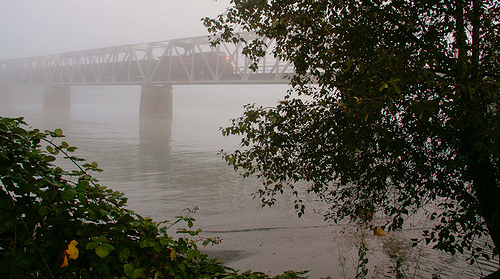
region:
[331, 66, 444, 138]
the tree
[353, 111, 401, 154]
the tree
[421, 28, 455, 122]
the tree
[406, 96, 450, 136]
the tree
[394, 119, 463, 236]
the tree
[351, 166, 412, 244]
the tree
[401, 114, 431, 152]
the tree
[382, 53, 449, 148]
the tree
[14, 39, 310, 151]
train bridge on the fog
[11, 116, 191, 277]
wet and green leaved bush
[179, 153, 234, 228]
ripples ans waves in the water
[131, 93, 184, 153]
pylon holding up the bridge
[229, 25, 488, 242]
tree near the river bank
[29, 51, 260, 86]
train driving over the bridge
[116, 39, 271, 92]
triangular design on the train bridge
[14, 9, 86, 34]
gray and foggy sky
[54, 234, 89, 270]
yellow leaf among the green ones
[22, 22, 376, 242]
foggy day by the river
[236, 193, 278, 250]
The water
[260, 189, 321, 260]
The water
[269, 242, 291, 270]
The water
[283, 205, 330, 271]
The water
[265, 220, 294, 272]
The water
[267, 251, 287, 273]
The water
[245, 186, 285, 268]
The water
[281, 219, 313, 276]
The water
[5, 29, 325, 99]
long covered bridge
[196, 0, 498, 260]
lush dense green trees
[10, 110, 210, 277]
dense green leafy bushes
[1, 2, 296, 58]
foggy gray misty sky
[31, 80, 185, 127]
grey concrete misty bridge supports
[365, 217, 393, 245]
yellow hanging tree leaf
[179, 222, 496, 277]
ripples on the river shore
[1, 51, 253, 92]
train travelling through the misty fog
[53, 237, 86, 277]
yellowed leaf on the green bushes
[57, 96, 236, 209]
ripples in the grey dirty water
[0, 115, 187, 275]
Green shrubery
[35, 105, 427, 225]
Large body of water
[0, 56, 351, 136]
Elevated train track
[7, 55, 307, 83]
Red train crossing over water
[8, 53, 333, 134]
Bridge Pilings over water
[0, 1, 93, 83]
Foggy day across water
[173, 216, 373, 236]
Stick floating in the river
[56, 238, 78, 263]
yellow leaf on a shrub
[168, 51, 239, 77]
Lights on a red train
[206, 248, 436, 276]
Edge of a body of water